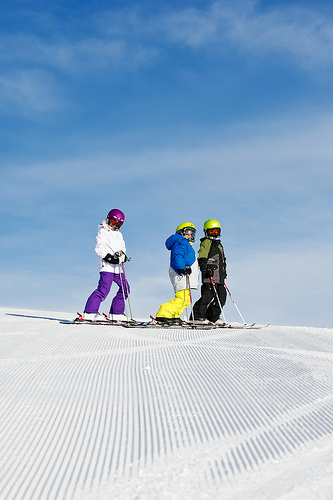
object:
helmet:
[108, 209, 125, 229]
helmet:
[204, 219, 223, 233]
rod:
[117, 261, 130, 324]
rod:
[123, 267, 142, 319]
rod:
[184, 275, 196, 327]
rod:
[211, 276, 230, 325]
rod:
[223, 280, 252, 325]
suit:
[191, 237, 227, 321]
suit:
[154, 233, 199, 319]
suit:
[83, 222, 130, 318]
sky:
[0, 0, 332, 330]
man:
[189, 219, 228, 323]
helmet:
[179, 221, 197, 235]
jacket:
[95, 222, 129, 274]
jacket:
[164, 233, 198, 275]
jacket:
[197, 235, 229, 284]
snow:
[0, 308, 333, 499]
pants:
[83, 273, 130, 315]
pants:
[156, 290, 194, 321]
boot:
[85, 312, 104, 320]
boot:
[107, 313, 128, 321]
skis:
[75, 314, 269, 331]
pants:
[188, 282, 228, 320]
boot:
[155, 317, 171, 325]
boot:
[176, 317, 188, 325]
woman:
[156, 222, 202, 323]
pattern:
[5, 329, 332, 497]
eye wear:
[110, 219, 121, 228]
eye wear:
[185, 229, 194, 234]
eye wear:
[208, 228, 219, 232]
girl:
[82, 208, 132, 323]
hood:
[97, 218, 111, 230]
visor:
[108, 216, 124, 230]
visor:
[206, 228, 222, 236]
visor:
[184, 227, 196, 242]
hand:
[104, 253, 119, 265]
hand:
[181, 267, 193, 275]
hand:
[204, 269, 214, 279]